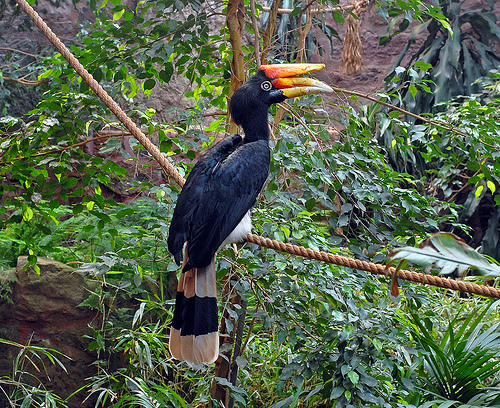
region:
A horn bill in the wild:
[169, 53, 332, 368]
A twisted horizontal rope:
[14, 0, 498, 314]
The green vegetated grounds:
[0, 0, 498, 407]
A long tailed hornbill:
[170, 63, 329, 364]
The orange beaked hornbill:
[171, 59, 333, 362]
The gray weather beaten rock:
[14, 253, 85, 326]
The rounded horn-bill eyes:
[258, 79, 275, 94]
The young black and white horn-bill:
[156, 53, 334, 368]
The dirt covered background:
[0, 0, 498, 407]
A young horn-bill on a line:
[19, 0, 497, 367]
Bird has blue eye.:
[258, 80, 268, 90]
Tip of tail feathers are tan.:
[167, 333, 219, 363]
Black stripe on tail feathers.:
[169, 296, 223, 324]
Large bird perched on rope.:
[159, 158, 284, 264]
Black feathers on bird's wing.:
[213, 161, 229, 265]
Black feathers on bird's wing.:
[178, 161, 198, 248]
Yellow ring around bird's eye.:
[257, 79, 275, 100]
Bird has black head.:
[221, 83, 256, 117]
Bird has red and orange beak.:
[267, 65, 332, 102]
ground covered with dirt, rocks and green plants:
[12, 8, 474, 393]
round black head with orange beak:
[225, 70, 330, 125]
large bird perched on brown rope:
[120, 55, 330, 280]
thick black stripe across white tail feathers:
[165, 250, 220, 365]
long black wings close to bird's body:
[160, 130, 273, 270]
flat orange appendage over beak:
[230, 60, 335, 100]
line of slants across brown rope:
[255, 230, 370, 270]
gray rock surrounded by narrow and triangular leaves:
[0, 225, 135, 400]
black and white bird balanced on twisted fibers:
[165, 60, 330, 365]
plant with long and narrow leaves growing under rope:
[401, 250, 496, 405]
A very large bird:
[150, 30, 386, 370]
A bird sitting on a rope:
[107, 12, 367, 386]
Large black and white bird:
[128, 48, 353, 393]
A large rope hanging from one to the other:
[23, 17, 174, 199]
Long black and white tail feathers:
[165, 257, 232, 392]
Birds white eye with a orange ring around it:
[245, 69, 284, 103]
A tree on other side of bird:
[208, 4, 369, 64]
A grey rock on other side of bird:
[6, 209, 134, 373]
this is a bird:
[132, 20, 417, 337]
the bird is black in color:
[239, 155, 263, 190]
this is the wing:
[218, 159, 250, 208]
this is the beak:
[264, 62, 316, 92]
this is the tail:
[163, 275, 222, 368]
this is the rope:
[278, 235, 348, 285]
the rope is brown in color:
[289, 235, 342, 272]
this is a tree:
[358, 80, 450, 193]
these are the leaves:
[328, 339, 366, 395]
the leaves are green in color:
[301, 301, 347, 386]